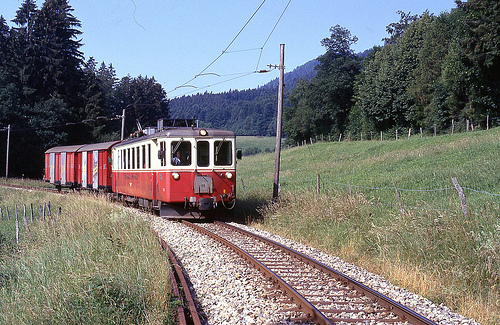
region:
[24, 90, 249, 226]
a red and white train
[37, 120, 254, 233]
a really old train on the traintrack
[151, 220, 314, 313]
a rusty train track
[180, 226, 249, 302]
rocks in the train tracks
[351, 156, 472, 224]
tall green grass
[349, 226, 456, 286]
dead brown grass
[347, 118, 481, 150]
a fence in front of tall trees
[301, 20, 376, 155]
a huge green tree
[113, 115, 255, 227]
the front of the train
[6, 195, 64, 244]
stakes in the ground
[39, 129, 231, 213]
red and white train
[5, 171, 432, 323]
train tracks on floor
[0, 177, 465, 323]
stone path on trains track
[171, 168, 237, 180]
two small front lights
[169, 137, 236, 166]
three windshields on front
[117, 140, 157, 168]
windows in the right side of train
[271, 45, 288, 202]
gray metal pole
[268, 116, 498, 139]
large metal fence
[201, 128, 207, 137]
front light above windshields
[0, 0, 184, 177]
big trees in the back of train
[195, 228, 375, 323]
train track in the forest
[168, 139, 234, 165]
front glass with wiper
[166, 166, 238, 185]
head light of the train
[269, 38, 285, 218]
electric pole with electric wires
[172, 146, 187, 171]
driver inside the train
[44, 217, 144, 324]
grass near the train track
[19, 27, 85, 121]
trees with branches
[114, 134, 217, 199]
red and white color train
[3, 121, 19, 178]
electric pole near the tree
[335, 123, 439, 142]
steel fencing with stone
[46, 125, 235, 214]
white and red train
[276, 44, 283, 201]
grey wood electrical pole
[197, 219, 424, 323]
wood and metal train tracks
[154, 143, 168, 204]
red and white door on train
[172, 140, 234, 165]
wind shield on train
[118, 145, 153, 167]
windows on side of train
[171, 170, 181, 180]
round headlight on train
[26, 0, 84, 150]
evergreen tree by tracks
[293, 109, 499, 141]
wire and wood fence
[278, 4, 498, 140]
trees by train tracks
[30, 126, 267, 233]
a short train on tracks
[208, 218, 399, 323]
empty tracks in front of train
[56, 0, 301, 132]
wires abov ethe tain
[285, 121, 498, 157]
a fence line by the trees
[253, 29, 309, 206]
a pole holding wires above train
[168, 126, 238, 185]
three head lights on train are on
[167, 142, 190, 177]
the conductor of train seen through window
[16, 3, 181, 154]
large trees behind train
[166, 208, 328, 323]
white rocks around tracks